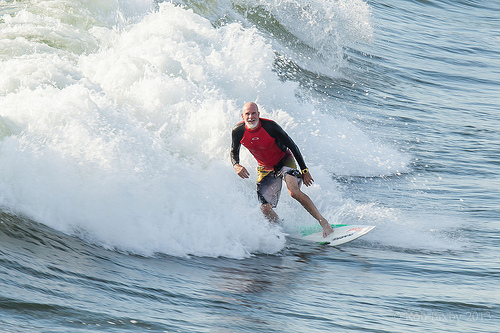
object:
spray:
[74, 60, 219, 180]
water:
[382, 60, 499, 268]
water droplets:
[393, 169, 402, 179]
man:
[229, 101, 332, 236]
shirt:
[230, 117, 306, 170]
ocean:
[336, 1, 499, 332]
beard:
[242, 117, 260, 129]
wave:
[0, 0, 408, 258]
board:
[297, 222, 376, 245]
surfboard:
[297, 223, 377, 246]